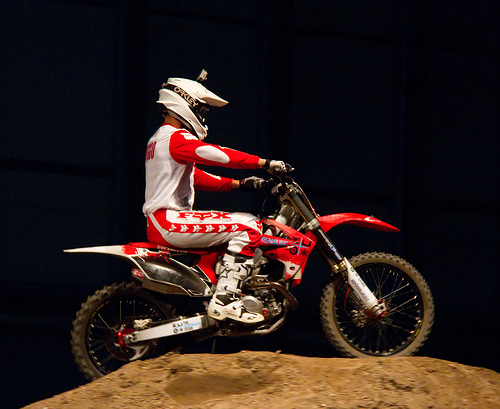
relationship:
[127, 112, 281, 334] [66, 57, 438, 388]
suit matches bike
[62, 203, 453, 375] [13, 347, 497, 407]
bike on a hill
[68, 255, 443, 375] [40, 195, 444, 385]
two wheels on a bike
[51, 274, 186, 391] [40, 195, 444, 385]
wheel on a bike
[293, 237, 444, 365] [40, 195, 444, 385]
wheel on a bike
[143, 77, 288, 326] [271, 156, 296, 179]
rider wearing gloves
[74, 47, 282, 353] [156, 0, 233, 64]
rider wearing helmet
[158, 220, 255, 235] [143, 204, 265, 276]
red stripe on pants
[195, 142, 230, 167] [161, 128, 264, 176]
patch on sleeve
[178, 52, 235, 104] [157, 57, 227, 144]
camera on helmet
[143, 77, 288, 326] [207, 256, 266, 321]
rider wearing boots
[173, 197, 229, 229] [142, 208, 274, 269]
word on pants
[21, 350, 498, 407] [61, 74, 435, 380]
dirt below motorcycle